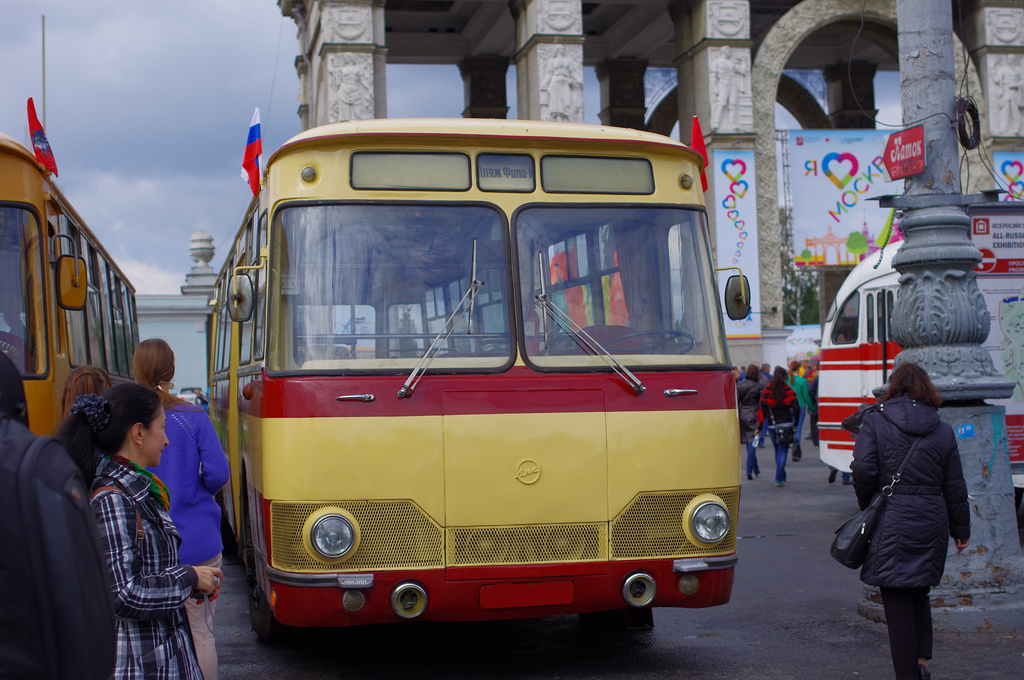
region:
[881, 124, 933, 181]
Red arrow shaped sign on the post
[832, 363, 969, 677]
Woman wearing a dark purple coat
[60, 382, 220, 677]
Woman wearing a long plaid coat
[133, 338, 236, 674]
Woman wearing a long sleeved purple shirt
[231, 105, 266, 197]
Red, white, and blue flag on the bus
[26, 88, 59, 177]
Red flag on the top of the bus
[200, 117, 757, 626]
Red and yellow bus between the people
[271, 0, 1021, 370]
Gray building located behind the bus.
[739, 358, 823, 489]
People walking behind the bus towards the building.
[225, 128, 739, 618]
a yellow and red bus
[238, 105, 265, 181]
a flag on the bus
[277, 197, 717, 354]
the windshield of the bus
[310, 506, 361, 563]
the headlight of the bus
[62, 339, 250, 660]
people standing by the bus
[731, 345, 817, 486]
people walking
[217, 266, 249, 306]
the mirror on the bus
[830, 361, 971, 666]
a person in a black coat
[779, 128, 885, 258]
a sign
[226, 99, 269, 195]
flag on top of the bus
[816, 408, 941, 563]
bag wrapped around the shoulder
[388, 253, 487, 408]
windshield wiper on the front of the bus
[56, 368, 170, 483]
dak hair is pulled back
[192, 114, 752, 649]
red and yellow bus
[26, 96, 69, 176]
red and blue flag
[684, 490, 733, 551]
circular light on the front of the bus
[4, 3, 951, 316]
sky is covered in clouds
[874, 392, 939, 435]
hood on the back of the jacket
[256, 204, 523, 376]
glass window on the yellow bus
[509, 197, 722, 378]
glass window on the yellow bus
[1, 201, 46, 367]
glass window on the yellow bus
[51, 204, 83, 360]
glass window on the yellow bus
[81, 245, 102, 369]
glass window on the yellow bus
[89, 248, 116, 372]
glass window on the yellow bus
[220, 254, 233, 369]
glass window on the yellow bus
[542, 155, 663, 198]
glass window on the yellow bus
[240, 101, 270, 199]
flag on roof of bus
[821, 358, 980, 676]
woman carrying purse walking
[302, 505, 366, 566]
headlight of yellow bus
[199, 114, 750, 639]
empty yellow bus parked on concrete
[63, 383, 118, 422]
blue bow in woman's hair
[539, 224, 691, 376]
a window on the bus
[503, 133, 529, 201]
a window on the bus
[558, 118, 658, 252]
a window on the bus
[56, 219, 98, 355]
a window on the bus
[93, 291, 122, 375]
a window on the bus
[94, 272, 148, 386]
a window on the bus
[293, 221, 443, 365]
a window on the bus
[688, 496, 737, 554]
clear headlight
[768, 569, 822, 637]
the ground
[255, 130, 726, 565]
a bus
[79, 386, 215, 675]
a women standing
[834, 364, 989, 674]
a women walking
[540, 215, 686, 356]
the windshield on the bus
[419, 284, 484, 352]
a windshiled wiper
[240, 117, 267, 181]
a flag on the bus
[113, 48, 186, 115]
a cloud in the sky